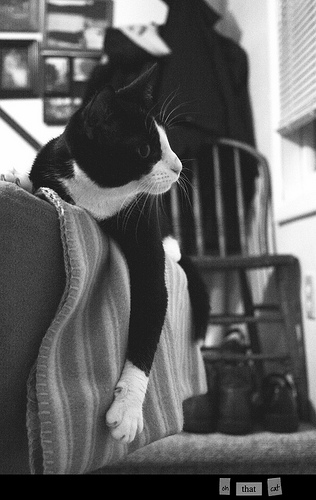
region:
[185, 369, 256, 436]
A pair of new work boots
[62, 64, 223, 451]
A cat pondering the meaning of life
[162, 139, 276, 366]
an old wooden chair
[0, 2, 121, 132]
Picture frames of family members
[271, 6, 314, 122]
White blinds across the window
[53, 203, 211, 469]
A wool pin-stripe blanket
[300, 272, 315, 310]
A wall socket outlet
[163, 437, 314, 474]
The brown shaded carpet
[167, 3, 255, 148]
A coat on a coat hanger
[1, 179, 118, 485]
The armrest of a couch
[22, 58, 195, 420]
a cat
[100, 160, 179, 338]
a cat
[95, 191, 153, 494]
a cat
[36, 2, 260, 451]
black and white photograph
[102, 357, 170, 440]
black cat with white paws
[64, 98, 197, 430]
black and white cat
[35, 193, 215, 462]
cat sitting on striped blanket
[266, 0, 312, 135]
mini blind covering windows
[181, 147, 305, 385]
brown wooden chair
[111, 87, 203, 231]
white whiskers on ca's face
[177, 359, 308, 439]
black shoes lined up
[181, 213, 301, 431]
shoes under chair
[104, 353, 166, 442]
cat's white paw with nails out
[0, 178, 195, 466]
backplate of a couch where cat is lying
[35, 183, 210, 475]
bath towell with lines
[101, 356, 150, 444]
black part of a leg of a cat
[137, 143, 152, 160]
big black and yellow right eye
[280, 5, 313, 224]
white window in the wall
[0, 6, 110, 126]
four pictures hanging in the wall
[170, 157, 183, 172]
small pinky nose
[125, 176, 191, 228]
white whiskers in the trunk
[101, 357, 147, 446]
white leg of a cat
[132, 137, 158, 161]
big black and yellow right eye of a cat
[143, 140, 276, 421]
brown wooden chair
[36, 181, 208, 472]
bath towel where cat is lying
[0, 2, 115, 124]
four pictures hagin in the wall